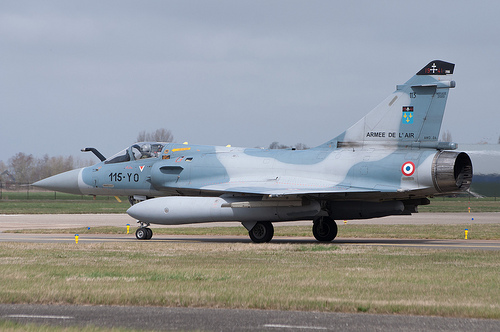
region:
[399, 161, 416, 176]
dart circle on plane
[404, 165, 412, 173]
blue dot on circle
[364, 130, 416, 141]
black letters on plane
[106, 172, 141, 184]
black numbers & letters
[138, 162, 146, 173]
white triangle on plane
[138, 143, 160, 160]
pilot sitting in plane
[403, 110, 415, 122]
yellow arrows on plane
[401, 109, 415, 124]
arrows on blue color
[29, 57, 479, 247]
plane has camouflage pattern on it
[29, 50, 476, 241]
a fighter jet on a runway.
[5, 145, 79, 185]
a forest full of green trees.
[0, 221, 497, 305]
A field full of green grass.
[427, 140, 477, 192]
a jet engine on a jet.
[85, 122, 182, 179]
a cock pit on a jet.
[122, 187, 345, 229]
a fuel tank on the bottom of a jet.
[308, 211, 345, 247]
landing gear on a fighter jet.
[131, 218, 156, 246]
front landing gear on a jet.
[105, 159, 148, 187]
ID number on a fighter jet.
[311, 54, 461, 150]
a tail wing on a fighter jet.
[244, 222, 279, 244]
wheel on the plane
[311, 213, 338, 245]
wheel on the plane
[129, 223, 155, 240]
wheel on the plane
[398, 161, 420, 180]
design on the plane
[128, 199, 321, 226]
missle on the jet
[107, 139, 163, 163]
cockpit on the jet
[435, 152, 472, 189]
engine on the jet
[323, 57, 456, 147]
tail fin on the jet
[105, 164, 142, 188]
number on the plane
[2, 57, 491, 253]
Plane sitting on a runway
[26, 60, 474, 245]
Man with gray helmet inside aircraft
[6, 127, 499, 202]
Line of leafless trees behind fence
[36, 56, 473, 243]
Plane with gray camouflage pattern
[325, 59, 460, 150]
Tail of plane with Armee de l'air written on it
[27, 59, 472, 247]
115-YO written under plane cockpit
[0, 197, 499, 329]
Dry green and brown grass bordering runway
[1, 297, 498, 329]
Dark gray paved road with white lines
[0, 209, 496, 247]
Runways lined with yellow and blue markers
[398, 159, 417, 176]
Bullseye emblem with red, white and blue paint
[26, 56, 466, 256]
a blue and white jet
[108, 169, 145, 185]
115-0 painted on the side of the jet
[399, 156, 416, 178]
a red, white, and blue logo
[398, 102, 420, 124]
a blue and yellow logo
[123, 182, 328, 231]
a large missle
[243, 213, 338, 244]
landing gears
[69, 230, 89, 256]
a yellow runway marker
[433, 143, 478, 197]
a jet exhaust hole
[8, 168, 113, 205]
a chain link fence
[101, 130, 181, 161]
a cockpit of a jet